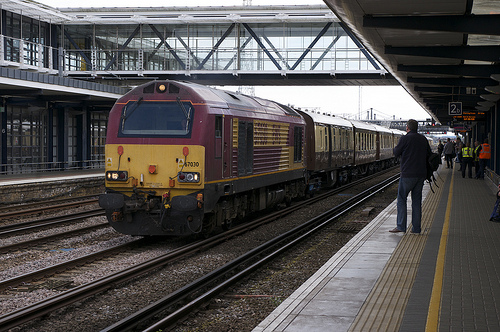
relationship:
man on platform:
[392, 120, 442, 235] [258, 150, 500, 331]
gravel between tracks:
[15, 237, 288, 310] [1, 140, 408, 331]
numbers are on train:
[177, 159, 205, 173] [98, 78, 459, 244]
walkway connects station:
[59, 7, 389, 85] [0, 2, 498, 331]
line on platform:
[432, 160, 459, 330] [258, 150, 500, 331]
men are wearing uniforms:
[455, 141, 500, 180] [460, 144, 493, 164]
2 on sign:
[449, 102, 459, 114] [447, 98, 463, 117]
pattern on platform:
[456, 208, 498, 281] [258, 150, 500, 331]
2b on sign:
[448, 102, 464, 115] [447, 98, 463, 117]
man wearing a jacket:
[474, 138, 494, 174] [478, 140, 493, 162]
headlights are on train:
[102, 170, 206, 185] [98, 78, 459, 244]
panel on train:
[106, 144, 207, 197] [98, 78, 459, 244]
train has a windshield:
[98, 78, 459, 244] [119, 98, 203, 141]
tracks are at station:
[1, 140, 408, 331] [0, 2, 498, 331]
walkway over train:
[59, 7, 389, 85] [98, 78, 459, 244]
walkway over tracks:
[59, 7, 389, 85] [1, 140, 408, 331]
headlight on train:
[99, 170, 130, 184] [98, 78, 459, 244]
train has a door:
[98, 78, 459, 244] [219, 114, 235, 180]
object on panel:
[145, 165, 161, 176] [106, 144, 207, 197]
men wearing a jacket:
[461, 141, 478, 180] [460, 144, 473, 162]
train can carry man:
[98, 78, 459, 244] [386, 118, 442, 233]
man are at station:
[386, 118, 442, 233] [0, 2, 498, 331]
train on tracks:
[98, 78, 459, 244] [1, 140, 408, 331]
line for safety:
[432, 160, 459, 330] [258, 150, 500, 331]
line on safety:
[432, 160, 459, 330] [258, 150, 500, 331]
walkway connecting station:
[59, 7, 389, 85] [0, 2, 498, 331]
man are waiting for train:
[386, 118, 442, 233] [98, 78, 459, 244]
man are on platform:
[386, 118, 442, 233] [258, 150, 500, 331]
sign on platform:
[447, 98, 463, 117] [258, 150, 500, 331]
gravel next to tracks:
[15, 237, 288, 310] [1, 140, 408, 331]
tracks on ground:
[1, 140, 408, 331] [4, 244, 262, 325]